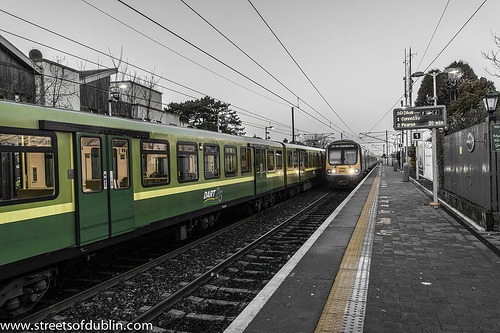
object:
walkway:
[225, 178, 498, 332]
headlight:
[349, 168, 355, 173]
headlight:
[331, 169, 336, 173]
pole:
[409, 69, 438, 205]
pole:
[400, 130, 403, 171]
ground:
[382, 213, 424, 300]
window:
[141, 138, 172, 188]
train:
[325, 139, 382, 189]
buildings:
[0, 35, 199, 130]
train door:
[252, 146, 258, 195]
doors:
[76, 131, 135, 246]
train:
[0, 99, 325, 318]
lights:
[7, 135, 127, 190]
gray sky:
[333, 2, 388, 107]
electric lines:
[0, 0, 499, 150]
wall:
[139, 94, 159, 118]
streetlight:
[480, 86, 499, 113]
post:
[392, 105, 447, 131]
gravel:
[93, 220, 271, 315]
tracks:
[0, 189, 333, 333]